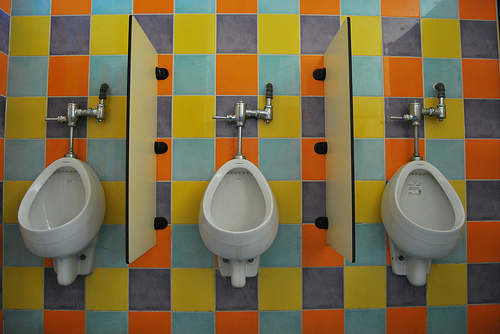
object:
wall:
[0, 0, 499, 334]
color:
[268, 25, 283, 43]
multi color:
[0, 0, 499, 333]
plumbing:
[41, 80, 109, 158]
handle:
[95, 82, 108, 99]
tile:
[168, 267, 218, 314]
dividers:
[321, 14, 359, 264]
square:
[213, 52, 259, 97]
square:
[216, 12, 258, 56]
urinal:
[195, 157, 281, 291]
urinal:
[14, 155, 108, 288]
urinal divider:
[123, 11, 161, 270]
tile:
[256, 135, 302, 184]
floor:
[3, 15, 470, 315]